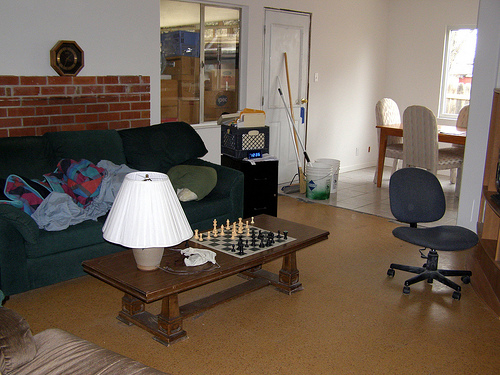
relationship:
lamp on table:
[99, 168, 195, 276] [75, 205, 335, 352]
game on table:
[188, 213, 299, 262] [75, 205, 335, 352]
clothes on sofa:
[3, 154, 158, 239] [1, 117, 246, 300]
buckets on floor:
[314, 154, 342, 196] [275, 156, 468, 234]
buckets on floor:
[303, 161, 335, 204] [275, 156, 468, 234]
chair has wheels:
[378, 167, 481, 303] [458, 273, 471, 285]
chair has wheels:
[378, 167, 481, 303] [450, 287, 461, 300]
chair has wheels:
[378, 167, 481, 303] [399, 282, 412, 296]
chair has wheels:
[378, 167, 481, 303] [384, 265, 395, 277]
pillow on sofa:
[162, 162, 220, 208] [1, 117, 246, 300]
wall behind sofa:
[1, 73, 155, 149] [1, 117, 246, 300]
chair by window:
[449, 100, 472, 188] [437, 20, 479, 124]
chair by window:
[371, 95, 417, 187] [437, 20, 479, 124]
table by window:
[371, 117, 472, 200] [437, 20, 479, 124]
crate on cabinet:
[215, 120, 273, 163] [219, 150, 282, 226]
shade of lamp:
[99, 170, 197, 253] [99, 168, 195, 276]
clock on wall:
[48, 36, 89, 80] [1, 73, 155, 149]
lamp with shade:
[99, 168, 195, 276] [99, 170, 197, 253]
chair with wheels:
[378, 167, 481, 303] [458, 273, 471, 285]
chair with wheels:
[378, 167, 481, 303] [450, 287, 461, 300]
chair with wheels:
[378, 167, 481, 303] [399, 282, 412, 296]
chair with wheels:
[378, 167, 481, 303] [384, 265, 395, 277]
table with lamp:
[75, 205, 335, 352] [99, 168, 195, 276]